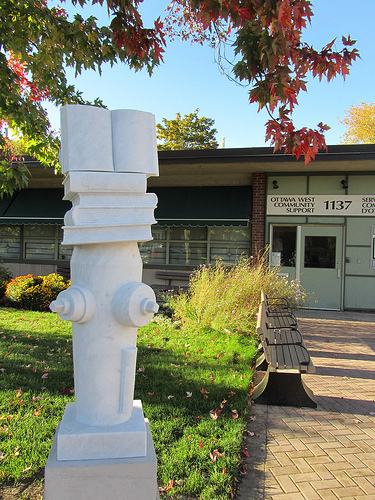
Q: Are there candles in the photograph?
A: No, there are no candles.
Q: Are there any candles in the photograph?
A: No, there are no candles.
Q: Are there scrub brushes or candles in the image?
A: No, there are no candles or scrub brushes.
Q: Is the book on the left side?
A: Yes, the book is on the left of the image.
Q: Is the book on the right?
A: No, the book is on the left of the image.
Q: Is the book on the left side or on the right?
A: The book is on the left of the image.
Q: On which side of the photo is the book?
A: The book is on the left of the image.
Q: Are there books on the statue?
A: Yes, there is a book on the statue.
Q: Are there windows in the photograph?
A: Yes, there are windows.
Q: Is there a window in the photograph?
A: Yes, there are windows.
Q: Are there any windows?
A: Yes, there are windows.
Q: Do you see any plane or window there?
A: Yes, there are windows.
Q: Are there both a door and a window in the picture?
A: Yes, there are both a window and a door.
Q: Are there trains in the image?
A: No, there are no trains.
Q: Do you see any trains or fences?
A: No, there are no trains or fences.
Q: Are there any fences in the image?
A: No, there are no fences.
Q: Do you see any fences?
A: No, there are no fences.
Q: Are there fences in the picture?
A: No, there are no fences.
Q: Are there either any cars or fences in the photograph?
A: No, there are no fences or cars.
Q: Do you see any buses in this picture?
A: No, there are no buses.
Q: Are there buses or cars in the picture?
A: No, there are no buses or cars.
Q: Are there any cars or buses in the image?
A: No, there are no buses or cars.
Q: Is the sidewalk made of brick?
A: Yes, the sidewalk is made of brick.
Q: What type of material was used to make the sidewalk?
A: The sidewalk is made of brick.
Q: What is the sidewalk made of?
A: The sidewalk is made of brick.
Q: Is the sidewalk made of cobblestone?
A: No, the sidewalk is made of brick.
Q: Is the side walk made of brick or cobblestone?
A: The side walk is made of brick.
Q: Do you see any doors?
A: Yes, there is a door.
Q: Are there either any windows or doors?
A: Yes, there is a door.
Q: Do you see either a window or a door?
A: Yes, there is a door.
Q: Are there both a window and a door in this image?
A: Yes, there are both a door and a window.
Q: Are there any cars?
A: No, there are no cars.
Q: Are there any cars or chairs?
A: No, there are no cars or chairs.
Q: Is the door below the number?
A: Yes, the door is below the number.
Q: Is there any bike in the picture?
A: No, there are no bikes.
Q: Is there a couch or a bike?
A: No, there are no bikes or couches.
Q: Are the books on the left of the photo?
A: Yes, the books are on the left of the image.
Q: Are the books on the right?
A: No, the books are on the left of the image.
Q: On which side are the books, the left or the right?
A: The books are on the left of the image.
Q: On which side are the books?
A: The books are on the left of the image.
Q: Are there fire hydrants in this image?
A: Yes, there is a fire hydrant.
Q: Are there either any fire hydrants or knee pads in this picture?
A: Yes, there is a fire hydrant.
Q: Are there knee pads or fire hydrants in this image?
A: Yes, there is a fire hydrant.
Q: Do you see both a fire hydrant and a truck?
A: No, there is a fire hydrant but no trucks.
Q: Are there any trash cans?
A: No, there are no trash cans.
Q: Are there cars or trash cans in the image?
A: No, there are no trash cans or cars.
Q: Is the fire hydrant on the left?
A: Yes, the fire hydrant is on the left of the image.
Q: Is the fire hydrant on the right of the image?
A: No, the fire hydrant is on the left of the image.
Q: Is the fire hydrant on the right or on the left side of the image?
A: The fire hydrant is on the left of the image.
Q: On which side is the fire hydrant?
A: The fire hydrant is on the left of the image.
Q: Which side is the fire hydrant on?
A: The fire hydrant is on the left of the image.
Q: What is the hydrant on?
A: The hydrant is on the statue.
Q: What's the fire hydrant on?
A: The hydrant is on the statue.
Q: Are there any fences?
A: No, there are no fences.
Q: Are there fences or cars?
A: No, there are no fences or cars.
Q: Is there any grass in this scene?
A: Yes, there is grass.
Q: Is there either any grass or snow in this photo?
A: Yes, there is grass.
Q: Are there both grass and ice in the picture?
A: No, there is grass but no ice.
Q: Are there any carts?
A: No, there are no carts.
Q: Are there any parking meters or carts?
A: No, there are no carts or parking meters.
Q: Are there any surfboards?
A: No, there are no surfboards.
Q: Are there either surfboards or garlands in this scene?
A: No, there are no surfboards or garlands.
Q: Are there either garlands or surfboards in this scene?
A: No, there are no surfboards or garlands.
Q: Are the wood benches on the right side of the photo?
A: Yes, the benches are on the right of the image.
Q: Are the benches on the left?
A: No, the benches are on the right of the image.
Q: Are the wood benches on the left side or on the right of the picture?
A: The benches are on the right of the image.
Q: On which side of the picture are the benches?
A: The benches are on the right of the image.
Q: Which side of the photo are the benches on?
A: The benches are on the right of the image.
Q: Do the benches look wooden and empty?
A: Yes, the benches are wooden and empty.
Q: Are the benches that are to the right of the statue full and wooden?
A: No, the benches are wooden but empty.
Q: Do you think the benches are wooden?
A: Yes, the benches are wooden.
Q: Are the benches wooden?
A: Yes, the benches are wooden.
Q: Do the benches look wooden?
A: Yes, the benches are wooden.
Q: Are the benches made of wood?
A: Yes, the benches are made of wood.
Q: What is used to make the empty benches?
A: The benches are made of wood.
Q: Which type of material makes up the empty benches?
A: The benches are made of wood.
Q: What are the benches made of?
A: The benches are made of wood.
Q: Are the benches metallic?
A: No, the benches are wooden.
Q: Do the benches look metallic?
A: No, the benches are wooden.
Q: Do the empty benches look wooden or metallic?
A: The benches are wooden.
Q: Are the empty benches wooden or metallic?
A: The benches are wooden.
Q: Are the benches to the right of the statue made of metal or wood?
A: The benches are made of wood.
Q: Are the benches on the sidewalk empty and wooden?
A: Yes, the benches are empty and wooden.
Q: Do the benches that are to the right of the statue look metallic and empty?
A: No, the benches are empty but wooden.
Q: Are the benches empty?
A: Yes, the benches are empty.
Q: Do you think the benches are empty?
A: Yes, the benches are empty.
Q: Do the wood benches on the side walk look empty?
A: Yes, the benches are empty.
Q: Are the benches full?
A: No, the benches are empty.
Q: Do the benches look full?
A: No, the benches are empty.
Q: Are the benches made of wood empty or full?
A: The benches are empty.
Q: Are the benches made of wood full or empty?
A: The benches are empty.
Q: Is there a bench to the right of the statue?
A: Yes, there are benches to the right of the statue.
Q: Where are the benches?
A: The benches are on the sidewalk.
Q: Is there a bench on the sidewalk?
A: Yes, there are benches on the sidewalk.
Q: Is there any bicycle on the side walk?
A: No, there are benches on the side walk.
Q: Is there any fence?
A: No, there are no fences.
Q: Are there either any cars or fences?
A: No, there are no fences or cars.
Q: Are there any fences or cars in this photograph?
A: No, there are no fences or cars.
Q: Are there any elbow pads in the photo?
A: No, there are no elbow pads.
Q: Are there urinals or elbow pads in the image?
A: No, there are no elbow pads or urinals.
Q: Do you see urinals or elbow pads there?
A: No, there are no elbow pads or urinals.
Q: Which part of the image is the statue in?
A: The statue is on the left of the image.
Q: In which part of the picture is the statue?
A: The statue is on the left of the image.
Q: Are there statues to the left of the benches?
A: Yes, there is a statue to the left of the benches.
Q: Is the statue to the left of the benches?
A: Yes, the statue is to the left of the benches.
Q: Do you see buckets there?
A: No, there are no buckets.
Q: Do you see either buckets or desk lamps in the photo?
A: No, there are no buckets or desk lamps.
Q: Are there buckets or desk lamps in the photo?
A: No, there are no buckets or desk lamps.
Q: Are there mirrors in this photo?
A: No, there are no mirrors.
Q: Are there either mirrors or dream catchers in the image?
A: No, there are no mirrors or dream catchers.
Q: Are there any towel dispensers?
A: No, there are no towel dispensers.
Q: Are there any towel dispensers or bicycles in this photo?
A: No, there are no towel dispensers or bicycles.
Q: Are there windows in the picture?
A: Yes, there is a window.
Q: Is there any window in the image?
A: Yes, there is a window.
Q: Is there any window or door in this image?
A: Yes, there is a window.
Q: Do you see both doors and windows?
A: Yes, there are both a window and a door.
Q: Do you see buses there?
A: No, there are no buses.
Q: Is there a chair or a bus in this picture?
A: No, there are no buses or chairs.